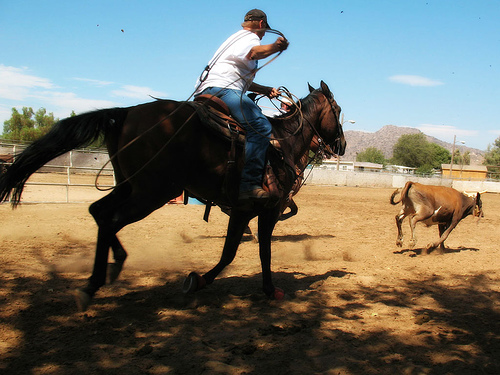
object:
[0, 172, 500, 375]
brown dirt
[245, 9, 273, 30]
cap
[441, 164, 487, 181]
brown building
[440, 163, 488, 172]
gray roof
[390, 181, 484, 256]
cow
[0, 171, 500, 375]
ground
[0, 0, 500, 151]
blue sky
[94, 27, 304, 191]
lasso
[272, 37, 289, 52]
right hand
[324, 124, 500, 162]
hill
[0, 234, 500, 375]
shadow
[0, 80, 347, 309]
horse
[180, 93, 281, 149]
saddle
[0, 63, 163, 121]
clouds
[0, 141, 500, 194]
fence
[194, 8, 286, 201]
man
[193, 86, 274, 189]
jeans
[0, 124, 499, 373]
background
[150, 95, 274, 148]
horseback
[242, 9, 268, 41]
head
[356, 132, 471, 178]
trees